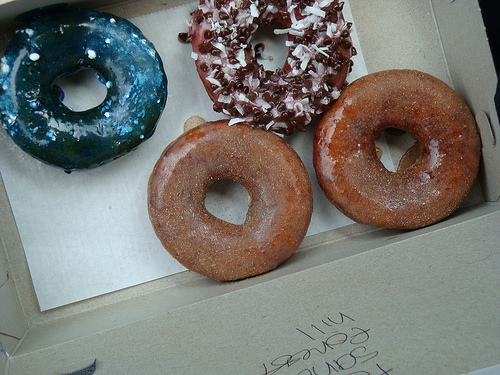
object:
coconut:
[273, 27, 305, 37]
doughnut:
[181, 0, 357, 140]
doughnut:
[0, 11, 167, 174]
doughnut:
[145, 115, 314, 282]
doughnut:
[316, 65, 479, 230]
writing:
[263, 313, 391, 374]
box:
[0, 0, 499, 373]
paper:
[0, 0, 398, 311]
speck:
[314, 45, 328, 56]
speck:
[294, 101, 305, 113]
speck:
[207, 74, 220, 90]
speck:
[214, 37, 228, 54]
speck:
[250, 3, 262, 21]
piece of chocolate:
[272, 83, 283, 95]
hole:
[251, 19, 292, 74]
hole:
[50, 56, 107, 111]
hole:
[199, 175, 252, 226]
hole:
[371, 119, 422, 173]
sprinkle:
[28, 50, 41, 64]